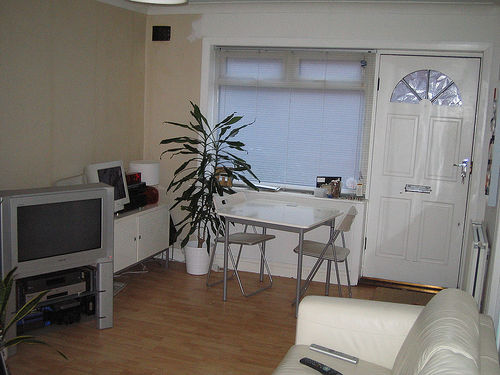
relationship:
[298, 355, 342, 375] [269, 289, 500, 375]
remote on couch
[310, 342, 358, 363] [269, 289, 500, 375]
remote on couch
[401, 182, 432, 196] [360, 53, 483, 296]
mail slot in door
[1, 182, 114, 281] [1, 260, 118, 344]
tv on stand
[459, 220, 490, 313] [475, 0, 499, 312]
vent near wall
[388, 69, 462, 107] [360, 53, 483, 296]
window on door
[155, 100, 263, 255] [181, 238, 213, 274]
plant in pot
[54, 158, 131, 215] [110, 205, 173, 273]
monitor on shelf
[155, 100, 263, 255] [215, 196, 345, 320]
plant near table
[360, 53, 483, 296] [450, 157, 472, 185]
door has knob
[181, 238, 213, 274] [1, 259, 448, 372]
pot on floor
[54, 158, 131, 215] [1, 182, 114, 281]
monitor behind tv